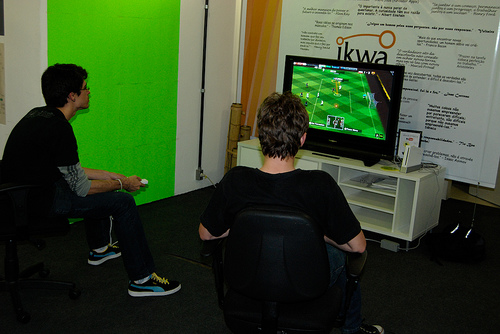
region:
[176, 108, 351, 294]
A man is visible.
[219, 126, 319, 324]
A man is visible.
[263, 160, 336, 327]
A man is visible.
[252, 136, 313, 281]
A man is visible.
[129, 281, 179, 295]
a boy is wearing black and blue shoes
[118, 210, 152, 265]
a boy is wearing blue jeans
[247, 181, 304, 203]
boy is wearing a black shirt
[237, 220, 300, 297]
the boy is sitting in a black chair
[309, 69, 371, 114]
the boys are playing a video game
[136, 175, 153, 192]
a white game controller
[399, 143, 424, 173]
a game system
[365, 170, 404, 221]
a white tv set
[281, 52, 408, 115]
a black flat screen television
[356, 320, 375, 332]
boy is wearing sneakers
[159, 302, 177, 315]
part of a floor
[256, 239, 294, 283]
part of a chair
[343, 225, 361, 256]
part of an elbow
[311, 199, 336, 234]
part of a shirt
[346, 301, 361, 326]
part of a jeans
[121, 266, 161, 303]
edge of a shoe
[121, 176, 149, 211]
part of a hand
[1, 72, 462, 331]
Two men in a room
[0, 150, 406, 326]
Two black chairs in the room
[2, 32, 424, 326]
Two kids playing Wii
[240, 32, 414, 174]
Flat screen tv on a stand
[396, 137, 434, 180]
White Wii next to the tv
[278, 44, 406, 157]
The kids are playing a soccer video game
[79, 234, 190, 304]
Black sneakers with white, blue and yellow accents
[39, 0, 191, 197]
Green paper on the white wall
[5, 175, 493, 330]
The floor is carpeted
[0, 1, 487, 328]
No women in the room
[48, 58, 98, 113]
Teen boys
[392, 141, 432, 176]
Nintendo Wii gaming system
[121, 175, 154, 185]
Nintendo Wiimote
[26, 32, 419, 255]
gaming as a study break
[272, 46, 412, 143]
FIFA gaming for Wii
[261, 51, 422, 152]
soccer video game for Wii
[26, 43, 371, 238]
Two teenage boys, playing Nintendo Wii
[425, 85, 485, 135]
Giant poster presentation for ikwa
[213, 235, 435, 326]
black swivel chairs for gaming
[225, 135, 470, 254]
entertainment system stand, furniture